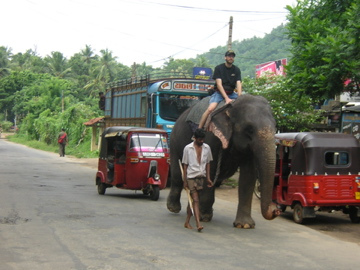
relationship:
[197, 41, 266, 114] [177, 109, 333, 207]
man on elephant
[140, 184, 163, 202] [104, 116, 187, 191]
wheel of taxi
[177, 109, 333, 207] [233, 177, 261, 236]
elephant has leg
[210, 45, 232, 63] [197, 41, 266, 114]
head on man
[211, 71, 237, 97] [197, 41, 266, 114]
arm on man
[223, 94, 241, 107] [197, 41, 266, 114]
hand on man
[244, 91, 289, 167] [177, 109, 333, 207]
head of elephant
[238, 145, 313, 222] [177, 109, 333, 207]
trunk of elephant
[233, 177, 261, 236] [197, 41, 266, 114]
leg of man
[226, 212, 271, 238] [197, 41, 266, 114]
foot of man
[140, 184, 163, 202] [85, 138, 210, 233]
wheel of car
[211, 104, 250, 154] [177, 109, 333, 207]
ear of elephant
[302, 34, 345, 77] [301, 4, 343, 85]
leaves on tree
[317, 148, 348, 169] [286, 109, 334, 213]
window on truck